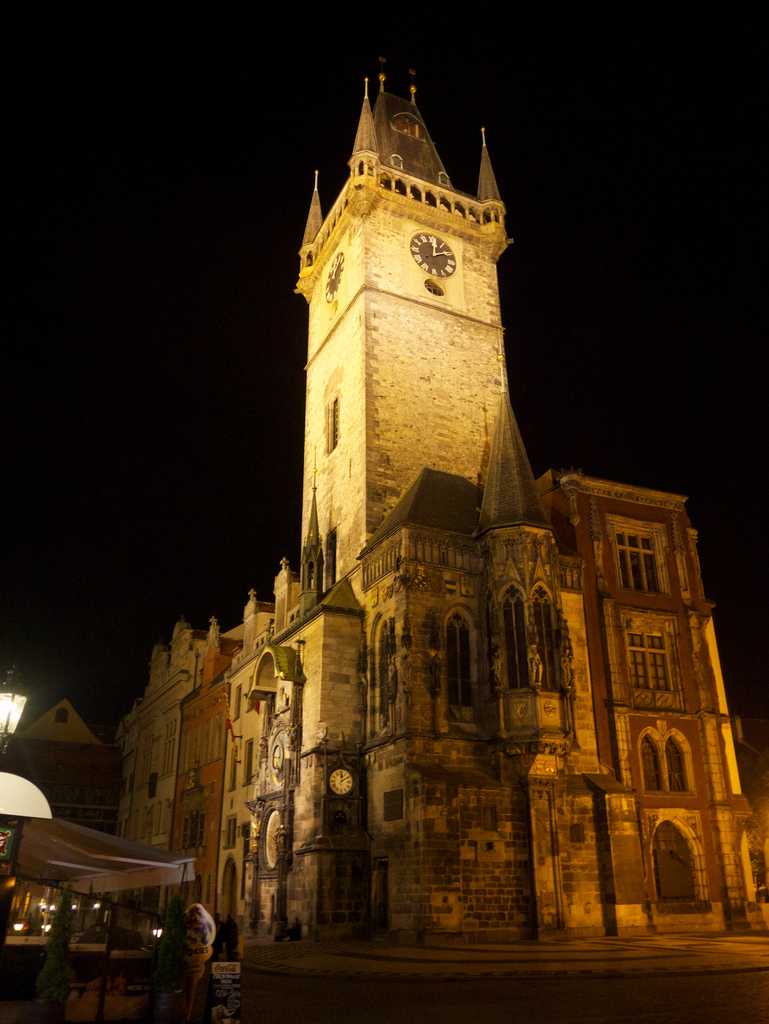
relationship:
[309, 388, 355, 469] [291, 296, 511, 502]
window on clock tower